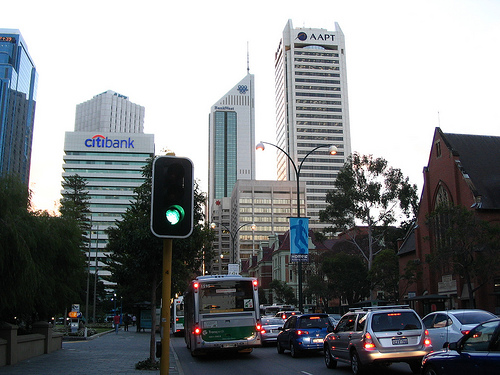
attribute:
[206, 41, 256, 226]
building —  white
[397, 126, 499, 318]
building — brick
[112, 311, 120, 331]
person — in red and blue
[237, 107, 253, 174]
wall — white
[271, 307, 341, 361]
car — small, blue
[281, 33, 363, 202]
building — large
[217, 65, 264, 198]
building — large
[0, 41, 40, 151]
building — large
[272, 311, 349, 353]
car — blue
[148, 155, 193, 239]
light — green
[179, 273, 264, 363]
bus —  the back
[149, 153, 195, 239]
traffic light — for traffic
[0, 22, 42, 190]
building — tall, blue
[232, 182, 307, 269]
building — large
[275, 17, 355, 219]
building — large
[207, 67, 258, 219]
building — large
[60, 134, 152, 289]
building — large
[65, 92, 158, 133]
building — large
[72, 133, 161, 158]
logo —  Citibank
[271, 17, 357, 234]
building —  of AAPT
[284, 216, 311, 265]
banner — blue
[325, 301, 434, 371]
car — parked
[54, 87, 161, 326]
office building — large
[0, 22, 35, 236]
building — large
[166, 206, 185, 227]
greenlight — green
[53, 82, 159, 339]
building — large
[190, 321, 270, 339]
lights — red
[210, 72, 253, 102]
top —  slanted